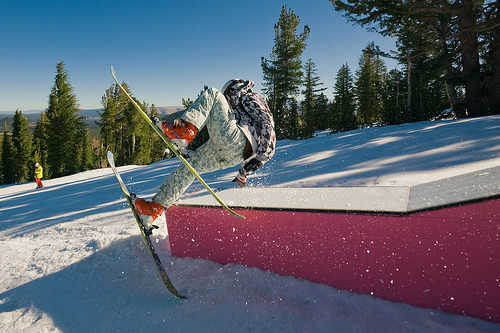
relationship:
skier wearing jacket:
[31, 161, 49, 191] [35, 166, 44, 181]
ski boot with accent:
[153, 114, 203, 152] [185, 130, 195, 136]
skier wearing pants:
[31, 161, 49, 191] [35, 177, 45, 188]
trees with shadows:
[5, 73, 171, 166] [17, 169, 155, 226]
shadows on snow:
[17, 169, 155, 226] [5, 123, 499, 333]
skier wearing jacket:
[101, 65, 279, 308] [224, 86, 283, 187]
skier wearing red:
[31, 161, 49, 191] [39, 184, 40, 185]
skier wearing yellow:
[31, 161, 49, 191] [40, 173, 41, 174]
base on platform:
[168, 216, 491, 308] [165, 158, 500, 330]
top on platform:
[179, 163, 499, 209] [165, 158, 500, 330]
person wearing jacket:
[31, 161, 49, 191] [35, 166, 44, 181]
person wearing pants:
[31, 161, 49, 191] [35, 177, 45, 188]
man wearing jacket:
[101, 65, 279, 308] [224, 86, 283, 187]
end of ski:
[110, 68, 120, 78] [109, 65, 245, 219]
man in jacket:
[31, 161, 49, 191] [35, 166, 44, 181]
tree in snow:
[260, 4, 314, 140] [5, 123, 499, 333]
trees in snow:
[5, 73, 171, 166] [5, 123, 499, 333]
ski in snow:
[106, 149, 192, 301] [5, 123, 499, 333]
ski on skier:
[109, 65, 245, 219] [31, 161, 49, 191]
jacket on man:
[35, 166, 44, 181] [31, 161, 49, 191]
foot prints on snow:
[299, 175, 386, 188] [5, 123, 499, 333]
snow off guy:
[248, 172, 269, 191] [101, 65, 279, 308]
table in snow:
[165, 158, 500, 330] [5, 123, 499, 333]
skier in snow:
[31, 161, 49, 191] [5, 123, 499, 333]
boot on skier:
[153, 114, 203, 152] [101, 65, 279, 308]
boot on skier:
[131, 195, 168, 230] [101, 65, 279, 308]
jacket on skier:
[35, 166, 44, 181] [31, 161, 49, 191]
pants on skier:
[35, 177, 45, 188] [31, 161, 49, 191]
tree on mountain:
[260, 4, 314, 140] [0, 116, 493, 332]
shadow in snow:
[383, 123, 493, 173] [5, 123, 499, 333]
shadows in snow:
[17, 169, 155, 226] [5, 123, 499, 333]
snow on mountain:
[5, 123, 499, 333] [0, 116, 493, 332]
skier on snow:
[101, 65, 279, 308] [5, 123, 499, 333]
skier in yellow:
[31, 161, 49, 191] [40, 173, 41, 174]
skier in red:
[31, 161, 49, 191] [39, 184, 40, 185]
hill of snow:
[0, 116, 493, 332] [5, 123, 499, 333]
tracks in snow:
[299, 175, 386, 188] [5, 123, 499, 333]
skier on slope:
[31, 161, 49, 191] [0, 116, 493, 332]